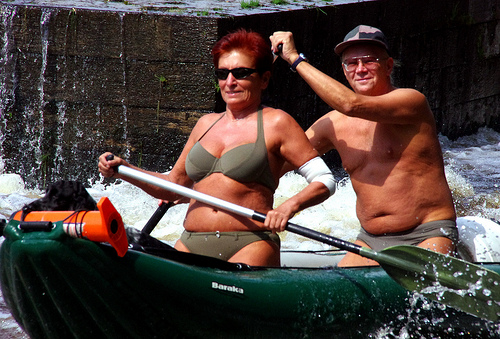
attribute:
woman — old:
[194, 29, 291, 262]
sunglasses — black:
[201, 59, 266, 81]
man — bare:
[308, 17, 462, 258]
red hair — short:
[208, 22, 267, 69]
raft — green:
[22, 233, 395, 334]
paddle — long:
[330, 236, 496, 329]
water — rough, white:
[447, 110, 488, 208]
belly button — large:
[363, 206, 394, 223]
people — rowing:
[139, 21, 473, 276]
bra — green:
[176, 122, 280, 187]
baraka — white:
[202, 279, 247, 298]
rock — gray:
[23, 0, 176, 150]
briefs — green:
[344, 219, 451, 243]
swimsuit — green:
[202, 104, 272, 264]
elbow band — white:
[299, 154, 341, 200]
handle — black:
[103, 154, 130, 175]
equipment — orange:
[16, 188, 133, 260]